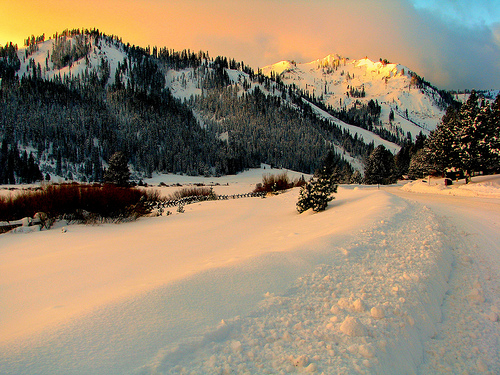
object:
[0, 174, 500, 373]
ground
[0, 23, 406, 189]
mountains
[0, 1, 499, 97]
sky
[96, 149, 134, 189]
trees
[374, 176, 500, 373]
pathway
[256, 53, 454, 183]
snow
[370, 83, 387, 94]
white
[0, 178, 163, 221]
bushes